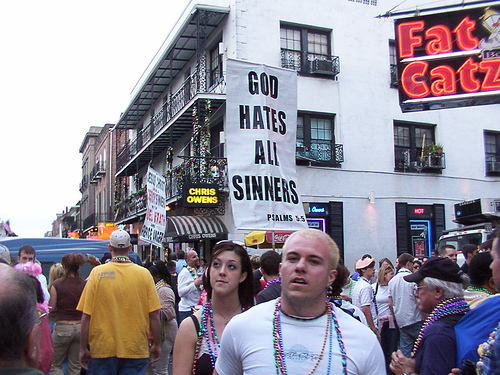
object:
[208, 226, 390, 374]
man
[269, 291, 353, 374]
beads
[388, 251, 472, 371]
man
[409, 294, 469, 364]
beads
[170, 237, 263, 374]
woman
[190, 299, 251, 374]
beads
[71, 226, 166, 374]
man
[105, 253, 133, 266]
beads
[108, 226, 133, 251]
cap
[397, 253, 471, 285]
cap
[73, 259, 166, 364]
shirt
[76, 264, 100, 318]
sleeve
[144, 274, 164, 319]
sleeve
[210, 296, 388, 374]
shirt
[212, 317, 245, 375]
sleeve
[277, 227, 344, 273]
hair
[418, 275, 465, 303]
hair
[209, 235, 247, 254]
glasses